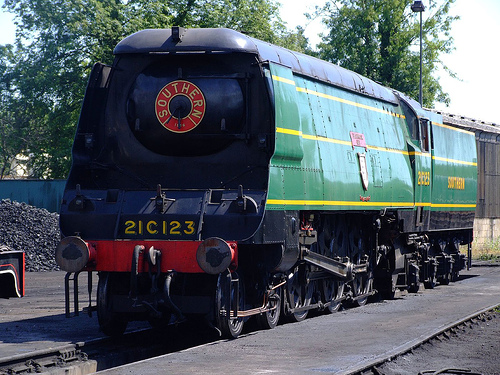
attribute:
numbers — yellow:
[120, 219, 196, 236]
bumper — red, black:
[85, 236, 289, 274]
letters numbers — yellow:
[121, 217, 197, 236]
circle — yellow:
[153, 77, 205, 132]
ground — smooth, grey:
[292, 246, 466, 374]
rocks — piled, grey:
[3, 195, 58, 267]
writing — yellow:
[136, 77, 274, 164]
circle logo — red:
[146, 70, 221, 142]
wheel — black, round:
[207, 277, 258, 342]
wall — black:
[181, 67, 254, 116]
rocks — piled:
[7, 201, 55, 241]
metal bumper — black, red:
[32, 218, 254, 307]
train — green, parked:
[52, 23, 482, 340]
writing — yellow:
[446, 175, 466, 190]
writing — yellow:
[415, 166, 432, 186]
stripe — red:
[82, 240, 236, 272]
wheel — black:
[222, 290, 244, 340]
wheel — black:
[257, 276, 281, 330]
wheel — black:
[282, 260, 315, 322]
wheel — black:
[318, 218, 347, 313]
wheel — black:
[349, 218, 377, 306]